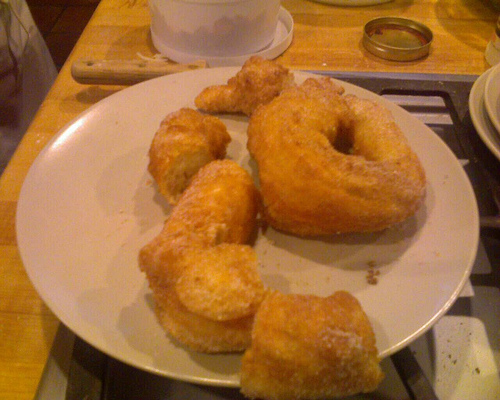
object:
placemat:
[33, 70, 500, 399]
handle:
[71, 55, 211, 86]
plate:
[483, 60, 500, 131]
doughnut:
[248, 75, 428, 231]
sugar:
[179, 191, 202, 216]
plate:
[16, 65, 481, 385]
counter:
[71, 0, 498, 83]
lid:
[360, 17, 435, 60]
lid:
[149, 6, 295, 67]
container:
[148, 0, 295, 65]